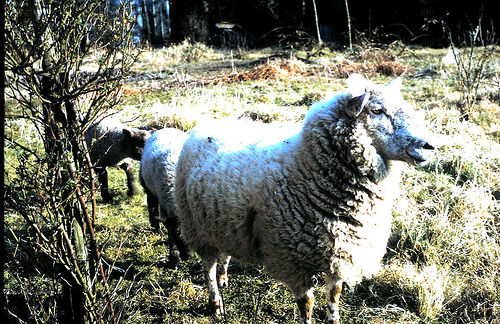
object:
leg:
[218, 250, 232, 281]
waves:
[103, 262, 188, 316]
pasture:
[3, 1, 499, 323]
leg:
[168, 230, 180, 260]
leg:
[94, 168, 108, 196]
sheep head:
[303, 76, 438, 167]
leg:
[160, 206, 169, 225]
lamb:
[141, 127, 192, 269]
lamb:
[139, 73, 436, 324]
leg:
[121, 162, 139, 195]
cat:
[84, 117, 158, 202]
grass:
[0, 41, 497, 322]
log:
[207, 53, 317, 65]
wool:
[186, 130, 341, 251]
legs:
[288, 277, 315, 324]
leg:
[147, 194, 161, 226]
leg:
[203, 254, 222, 305]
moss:
[201, 44, 416, 96]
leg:
[326, 267, 344, 319]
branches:
[10, 19, 72, 58]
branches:
[36, 145, 85, 317]